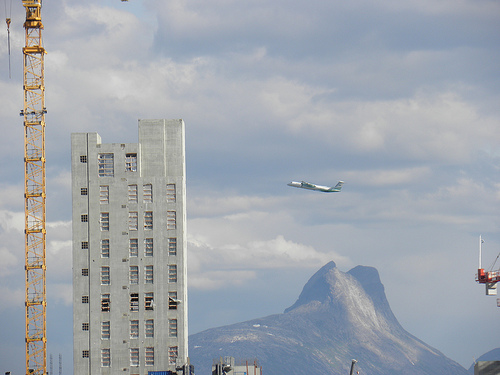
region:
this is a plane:
[286, 159, 364, 224]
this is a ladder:
[16, 3, 54, 373]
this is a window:
[94, 180, 112, 206]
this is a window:
[96, 209, 117, 236]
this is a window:
[79, 207, 87, 224]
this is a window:
[78, 235, 92, 252]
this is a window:
[76, 322, 93, 332]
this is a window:
[81, 347, 88, 361]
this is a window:
[78, 152, 85, 167]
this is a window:
[77, 185, 89, 197]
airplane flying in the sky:
[282, 177, 344, 195]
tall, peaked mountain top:
[293, 260, 390, 322]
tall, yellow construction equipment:
[18, 0, 50, 373]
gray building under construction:
[63, 113, 192, 374]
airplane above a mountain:
[279, 170, 394, 331]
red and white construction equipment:
[473, 228, 499, 305]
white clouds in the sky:
[7, 3, 498, 308]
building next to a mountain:
[63, 115, 400, 370]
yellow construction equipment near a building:
[18, 0, 54, 372]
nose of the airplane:
[286, 180, 292, 184]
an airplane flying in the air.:
[284, 174, 345, 198]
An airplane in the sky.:
[286, 177, 346, 196]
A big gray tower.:
[68, 115, 191, 373]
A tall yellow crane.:
[21, 0, 48, 373]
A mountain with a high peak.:
[189, 258, 470, 373]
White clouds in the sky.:
[0, 2, 499, 372]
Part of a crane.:
[474, 231, 499, 297]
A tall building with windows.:
[68, 115, 190, 372]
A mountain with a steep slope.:
[191, 258, 466, 374]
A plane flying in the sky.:
[284, 177, 343, 195]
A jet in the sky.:
[285, 177, 345, 197]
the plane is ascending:
[268, 145, 365, 208]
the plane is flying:
[245, 143, 398, 234]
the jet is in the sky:
[267, 143, 412, 212]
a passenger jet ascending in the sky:
[271, 155, 393, 230]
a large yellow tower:
[3, 0, 95, 372]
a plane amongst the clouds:
[207, 80, 467, 217]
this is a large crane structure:
[2, 5, 83, 374]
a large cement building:
[58, 93, 217, 371]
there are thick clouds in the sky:
[22, 3, 499, 193]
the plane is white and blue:
[282, 154, 385, 223]